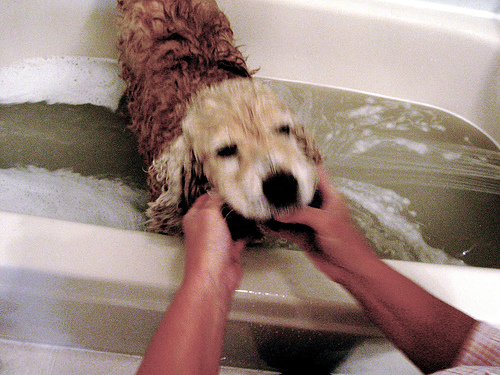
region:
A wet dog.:
[119, 1, 323, 236]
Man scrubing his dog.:
[176, 153, 367, 278]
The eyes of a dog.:
[210, 117, 297, 163]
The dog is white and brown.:
[116, 1, 326, 238]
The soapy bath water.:
[21, 81, 124, 226]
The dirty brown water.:
[12, 67, 96, 215]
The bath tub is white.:
[314, 8, 486, 110]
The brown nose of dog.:
[261, 170, 303, 216]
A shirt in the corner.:
[436, 314, 498, 374]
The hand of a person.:
[182, 196, 244, 287]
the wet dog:
[111, 2, 319, 216]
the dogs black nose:
[260, 173, 297, 204]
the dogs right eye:
[215, 143, 239, 157]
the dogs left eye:
[273, 122, 293, 134]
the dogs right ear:
[149, 139, 195, 236]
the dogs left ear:
[294, 117, 321, 159]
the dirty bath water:
[360, 98, 477, 218]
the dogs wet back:
[125, 2, 220, 90]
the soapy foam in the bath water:
[27, 56, 102, 98]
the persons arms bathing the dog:
[126, 167, 485, 373]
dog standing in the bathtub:
[110, 1, 332, 236]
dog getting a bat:
[114, 3, 355, 244]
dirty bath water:
[3, 46, 498, 266]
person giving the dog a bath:
[131, 113, 491, 373]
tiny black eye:
[214, 140, 238, 161]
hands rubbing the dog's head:
[143, 84, 370, 266]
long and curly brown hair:
[127, 81, 158, 143]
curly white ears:
[144, 133, 186, 233]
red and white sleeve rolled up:
[430, 316, 497, 373]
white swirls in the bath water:
[327, 87, 459, 180]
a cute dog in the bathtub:
[115, 1, 322, 234]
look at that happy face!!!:
[207, 117, 319, 221]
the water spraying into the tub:
[348, 125, 499, 188]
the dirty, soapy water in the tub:
[13, 78, 490, 264]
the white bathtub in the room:
[5, 3, 499, 359]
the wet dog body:
[108, 1, 248, 139]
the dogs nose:
[260, 168, 300, 209]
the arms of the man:
[158, 170, 490, 373]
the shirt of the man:
[429, 312, 499, 368]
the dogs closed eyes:
[208, 119, 298, 162]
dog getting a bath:
[107, 11, 336, 234]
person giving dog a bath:
[137, 207, 492, 373]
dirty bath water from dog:
[19, 100, 106, 175]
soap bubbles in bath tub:
[18, 61, 101, 98]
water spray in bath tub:
[377, 134, 497, 197]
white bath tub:
[11, 223, 145, 328]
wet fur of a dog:
[125, 19, 214, 87]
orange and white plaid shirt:
[449, 335, 496, 367]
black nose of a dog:
[259, 172, 299, 207]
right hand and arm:
[309, 182, 425, 354]